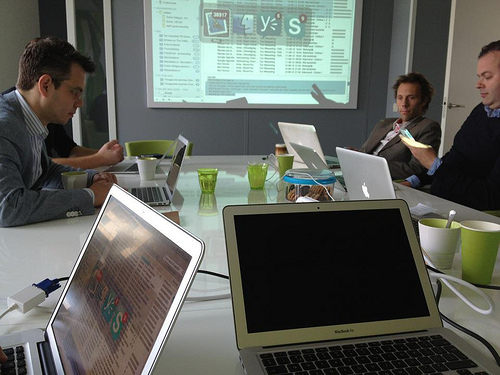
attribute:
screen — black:
[246, 227, 418, 310]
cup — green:
[195, 165, 220, 194]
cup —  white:
[133, 155, 156, 183]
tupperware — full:
[279, 161, 343, 212]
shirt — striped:
[15, 90, 51, 187]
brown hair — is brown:
[14, 36, 101, 96]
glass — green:
[191, 162, 224, 200]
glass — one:
[245, 160, 268, 191]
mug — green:
[267, 147, 295, 181]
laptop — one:
[220, 201, 495, 373]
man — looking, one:
[0, 34, 117, 227]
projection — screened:
[146, 0, 356, 105]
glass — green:
[197, 167, 217, 192]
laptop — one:
[82, 190, 196, 322]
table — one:
[143, 137, 425, 232]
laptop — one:
[103, 120, 206, 220]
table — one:
[3, 143, 498, 374]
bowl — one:
[286, 164, 335, 199]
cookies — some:
[287, 181, 332, 198]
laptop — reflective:
[2, 180, 209, 373]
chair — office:
[119, 146, 236, 213]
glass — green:
[191, 160, 228, 205]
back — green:
[119, 129, 197, 172]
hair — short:
[9, 28, 99, 106]